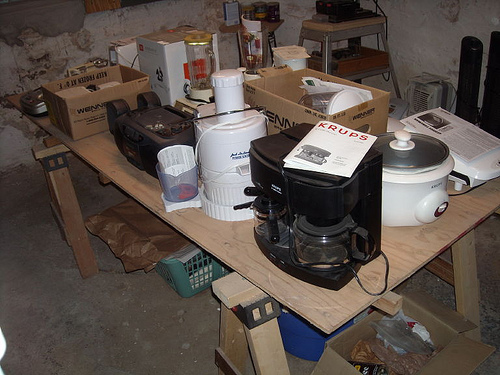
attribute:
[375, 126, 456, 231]
appliance — white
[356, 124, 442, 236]
pot — white 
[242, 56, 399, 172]
box — cardboard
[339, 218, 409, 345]
cord — black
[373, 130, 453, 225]
rice cooker — white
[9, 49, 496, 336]
table — makeshift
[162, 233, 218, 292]
basket — green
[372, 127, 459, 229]
crockpot — white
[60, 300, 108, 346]
ground — gray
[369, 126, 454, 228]
pot — crock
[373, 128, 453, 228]
rice maker — white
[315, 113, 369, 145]
krups — red